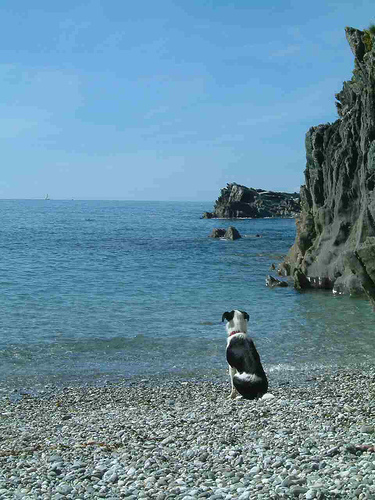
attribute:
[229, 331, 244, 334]
collar —  Red,  dog's, for neck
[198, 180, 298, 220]
formation —  Large, of rock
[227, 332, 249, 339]
fur —  White,  dog's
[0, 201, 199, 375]
water —  ocean's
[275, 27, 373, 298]
cliff — of rock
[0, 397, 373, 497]
beach —  rocky, w/ rocky shore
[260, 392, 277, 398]
tail —  dog's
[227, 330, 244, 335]
collar —  dog's,  red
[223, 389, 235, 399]
paw —  dog's, the left front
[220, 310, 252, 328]
head —  dog's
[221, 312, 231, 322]
ear —  dog's, the left  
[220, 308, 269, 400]
dog —  black and white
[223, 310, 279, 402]
dog — white and black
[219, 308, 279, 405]
dog — small, black and white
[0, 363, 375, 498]
stones — gray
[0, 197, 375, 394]
water — blue, rippled, light blue, large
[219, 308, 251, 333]
head — black and white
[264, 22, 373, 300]
rock — large, gray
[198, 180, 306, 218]
rock — large, gray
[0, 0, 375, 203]
sky — blue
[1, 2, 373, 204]
clouds — white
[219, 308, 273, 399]
dog — white, black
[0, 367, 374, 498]
beach — rocky